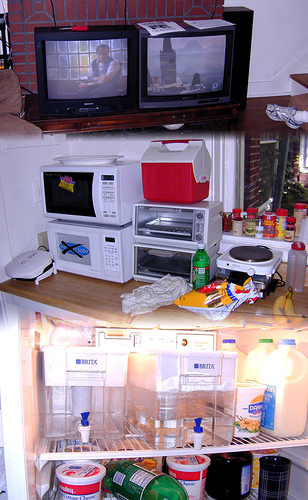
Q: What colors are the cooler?
A: Red and white.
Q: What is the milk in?
A: Refrigerator.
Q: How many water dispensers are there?
A: Two.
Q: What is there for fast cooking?
A: Microwave.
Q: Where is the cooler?
A: Top of the toaster oven.